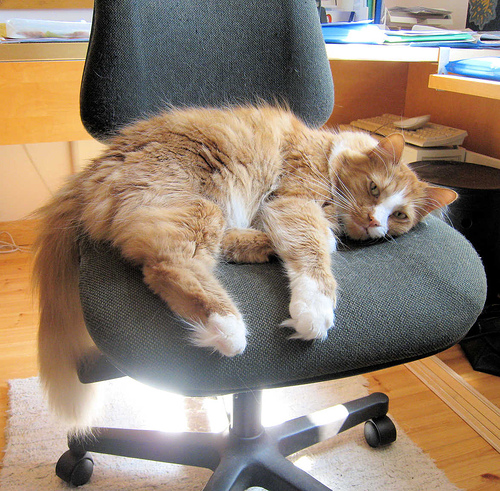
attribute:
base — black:
[53, 389, 395, 489]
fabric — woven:
[98, 19, 330, 134]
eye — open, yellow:
[368, 179, 380, 198]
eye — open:
[389, 210, 408, 221]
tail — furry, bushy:
[37, 221, 107, 441]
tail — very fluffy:
[40, 169, 90, 427]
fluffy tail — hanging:
[31, 197, 94, 458]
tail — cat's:
[22, 201, 93, 417]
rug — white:
[0, 375, 460, 490]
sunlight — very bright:
[59, 353, 366, 485]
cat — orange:
[170, 98, 413, 330]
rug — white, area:
[6, 362, 450, 489]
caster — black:
[59, 414, 221, 478]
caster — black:
[281, 392, 402, 457]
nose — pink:
[354, 191, 399, 240]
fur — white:
[286, 293, 322, 329]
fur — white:
[206, 321, 239, 349]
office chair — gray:
[53, 0, 488, 489]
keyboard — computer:
[350, 108, 468, 148]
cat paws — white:
[285, 272, 340, 344]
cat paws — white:
[182, 301, 249, 362]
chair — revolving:
[53, 0, 488, 490]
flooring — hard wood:
[0, 220, 499, 490]